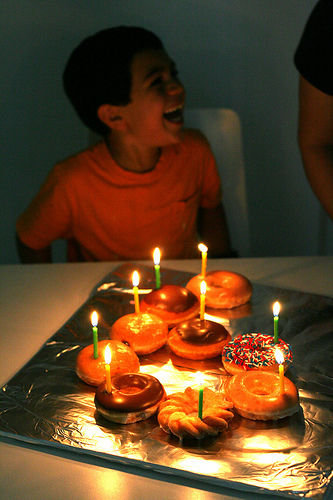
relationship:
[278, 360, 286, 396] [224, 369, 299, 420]
candle stuck on doughnut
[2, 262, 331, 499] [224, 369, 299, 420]
foil under doughnut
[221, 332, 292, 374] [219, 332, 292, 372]
doughnut has sprinkles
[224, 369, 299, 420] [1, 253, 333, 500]
doughnut sitting on table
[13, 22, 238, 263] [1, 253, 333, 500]
child sitting at table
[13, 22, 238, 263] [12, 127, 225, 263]
child wearing t-shirt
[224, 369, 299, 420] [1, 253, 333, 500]
doughnut laying in table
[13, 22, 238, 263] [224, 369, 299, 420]
child in front of doughnut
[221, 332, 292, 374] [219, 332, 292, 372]
doughnut with sprinkles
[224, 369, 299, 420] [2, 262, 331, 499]
doughnut sitting on foil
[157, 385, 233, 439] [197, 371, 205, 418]
cruller has candle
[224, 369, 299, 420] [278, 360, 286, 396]
doughnut has candle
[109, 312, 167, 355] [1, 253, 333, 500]
doughnut sitting on table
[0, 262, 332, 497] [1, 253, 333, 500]
pan sitting on table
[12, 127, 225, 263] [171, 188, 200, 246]
t-shirt has pocket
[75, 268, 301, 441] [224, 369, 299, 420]
number has doughnut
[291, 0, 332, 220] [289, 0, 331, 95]
arm wearing shirt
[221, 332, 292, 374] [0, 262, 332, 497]
doughnut sitting on pan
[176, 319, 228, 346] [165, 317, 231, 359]
chocolate covering doughnut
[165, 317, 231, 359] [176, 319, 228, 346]
doughnut covered with chocolate